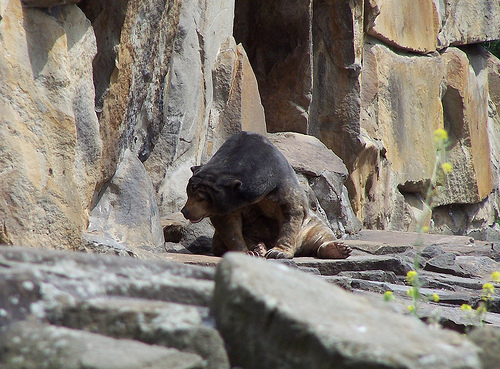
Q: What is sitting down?
A: The bear.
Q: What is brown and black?
A: The bear is.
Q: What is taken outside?
A: The bear picture.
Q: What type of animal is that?
A: A bear.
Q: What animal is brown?
A: The bear.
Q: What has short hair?
A: The bear.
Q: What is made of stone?
A: The wall is.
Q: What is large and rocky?
A: Mountain range.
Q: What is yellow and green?
A: Flowers.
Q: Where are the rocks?
A: Around the bear.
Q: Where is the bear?
A: On the rocky area.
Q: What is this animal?
A: Black bear.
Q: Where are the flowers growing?
A: Through the rocks.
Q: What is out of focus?
A: Rocks.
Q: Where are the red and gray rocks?
A: Side wall.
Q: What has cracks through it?
A: The wall.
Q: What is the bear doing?
A: Looking down.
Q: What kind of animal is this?
A: A bear.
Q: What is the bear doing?
A: Sitting.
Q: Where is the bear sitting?
A: On the rocks.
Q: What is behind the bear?
A: Rocks.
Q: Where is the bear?
A: On the rocks.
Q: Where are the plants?
A: Growing next to the rocks.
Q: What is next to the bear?
A: Rocks.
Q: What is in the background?
A: Rocks.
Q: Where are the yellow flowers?
A: Growing near the rocks.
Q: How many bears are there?
A: One.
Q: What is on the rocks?
A: The bear.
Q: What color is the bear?
A: Brown.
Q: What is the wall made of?
A: Rocks.